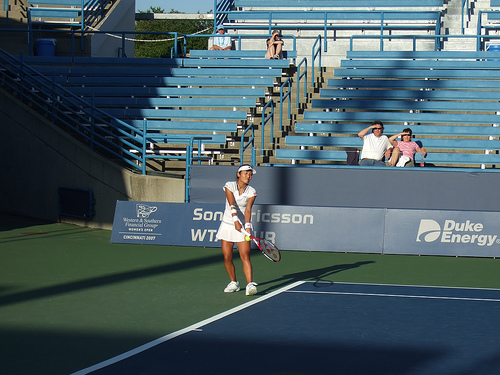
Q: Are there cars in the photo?
A: No, there are no cars.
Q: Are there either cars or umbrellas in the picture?
A: No, there are no cars or umbrellas.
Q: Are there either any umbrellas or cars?
A: No, there are no cars or umbrellas.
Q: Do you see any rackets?
A: Yes, there is a racket.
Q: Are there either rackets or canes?
A: Yes, there is a racket.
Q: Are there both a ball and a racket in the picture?
A: Yes, there are both a racket and a ball.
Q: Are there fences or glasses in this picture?
A: No, there are no glasses or fences.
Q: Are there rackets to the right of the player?
A: Yes, there is a racket to the right of the player.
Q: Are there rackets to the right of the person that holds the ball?
A: Yes, there is a racket to the right of the player.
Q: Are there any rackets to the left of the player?
A: No, the racket is to the right of the player.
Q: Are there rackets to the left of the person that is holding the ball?
A: No, the racket is to the right of the player.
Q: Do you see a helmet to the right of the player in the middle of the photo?
A: No, there is a racket to the right of the player.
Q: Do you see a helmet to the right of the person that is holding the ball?
A: No, there is a racket to the right of the player.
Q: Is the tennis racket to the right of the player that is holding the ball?
A: Yes, the tennis racket is to the right of the player.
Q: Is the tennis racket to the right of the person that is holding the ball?
A: Yes, the tennis racket is to the right of the player.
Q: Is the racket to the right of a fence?
A: No, the racket is to the right of the player.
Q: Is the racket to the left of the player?
A: No, the racket is to the right of the player.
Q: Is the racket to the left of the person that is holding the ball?
A: No, the racket is to the right of the player.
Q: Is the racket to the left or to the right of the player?
A: The racket is to the right of the player.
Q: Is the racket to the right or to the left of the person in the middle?
A: The racket is to the right of the player.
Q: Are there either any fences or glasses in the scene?
A: No, there are no glasses or fences.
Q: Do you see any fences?
A: No, there are no fences.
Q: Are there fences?
A: No, there are no fences.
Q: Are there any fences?
A: No, there are no fences.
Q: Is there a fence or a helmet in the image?
A: No, there are no fences or helmets.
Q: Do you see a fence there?
A: No, there are no fences.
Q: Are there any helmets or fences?
A: No, there are no fences or helmets.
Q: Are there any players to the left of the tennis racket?
A: Yes, there is a player to the left of the tennis racket.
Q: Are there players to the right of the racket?
A: No, the player is to the left of the racket.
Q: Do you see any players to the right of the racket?
A: No, the player is to the left of the racket.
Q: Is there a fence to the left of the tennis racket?
A: No, there is a player to the left of the tennis racket.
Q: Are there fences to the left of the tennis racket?
A: No, there is a player to the left of the tennis racket.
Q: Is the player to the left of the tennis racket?
A: Yes, the player is to the left of the tennis racket.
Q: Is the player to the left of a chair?
A: No, the player is to the left of the tennis racket.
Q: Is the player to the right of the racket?
A: No, the player is to the left of the racket.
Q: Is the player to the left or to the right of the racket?
A: The player is to the left of the racket.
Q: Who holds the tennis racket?
A: The player holds the tennis racket.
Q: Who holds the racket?
A: The player holds the tennis racket.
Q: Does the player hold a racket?
A: Yes, the player holds a racket.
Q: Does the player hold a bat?
A: No, the player holds a racket.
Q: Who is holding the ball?
A: The player is holding the ball.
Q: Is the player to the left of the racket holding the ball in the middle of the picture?
A: Yes, the player is holding the ball.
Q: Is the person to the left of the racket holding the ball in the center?
A: Yes, the player is holding the ball.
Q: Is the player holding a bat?
A: No, the player is holding the ball.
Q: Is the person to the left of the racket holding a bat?
A: No, the player is holding the ball.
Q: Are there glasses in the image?
A: No, there are no glasses.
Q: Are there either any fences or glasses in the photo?
A: No, there are no glasses or fences.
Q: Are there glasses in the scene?
A: No, there are no glasses.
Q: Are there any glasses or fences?
A: No, there are no glasses or fences.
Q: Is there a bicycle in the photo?
A: No, there are no bicycles.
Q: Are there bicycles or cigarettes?
A: No, there are no bicycles or cigarettes.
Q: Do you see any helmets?
A: No, there are no helmets.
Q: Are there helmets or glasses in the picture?
A: No, there are no helmets or glasses.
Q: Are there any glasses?
A: No, there are no glasses.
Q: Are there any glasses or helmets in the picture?
A: No, there are no glasses or helmets.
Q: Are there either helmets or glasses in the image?
A: No, there are no glasses or helmets.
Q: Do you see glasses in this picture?
A: No, there are no glasses.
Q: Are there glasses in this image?
A: No, there are no glasses.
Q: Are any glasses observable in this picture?
A: No, there are no glasses.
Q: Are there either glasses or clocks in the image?
A: No, there are no glasses or clocks.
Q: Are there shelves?
A: No, there are no shelves.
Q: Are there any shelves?
A: No, there are no shelves.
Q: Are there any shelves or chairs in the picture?
A: No, there are no shelves or chairs.